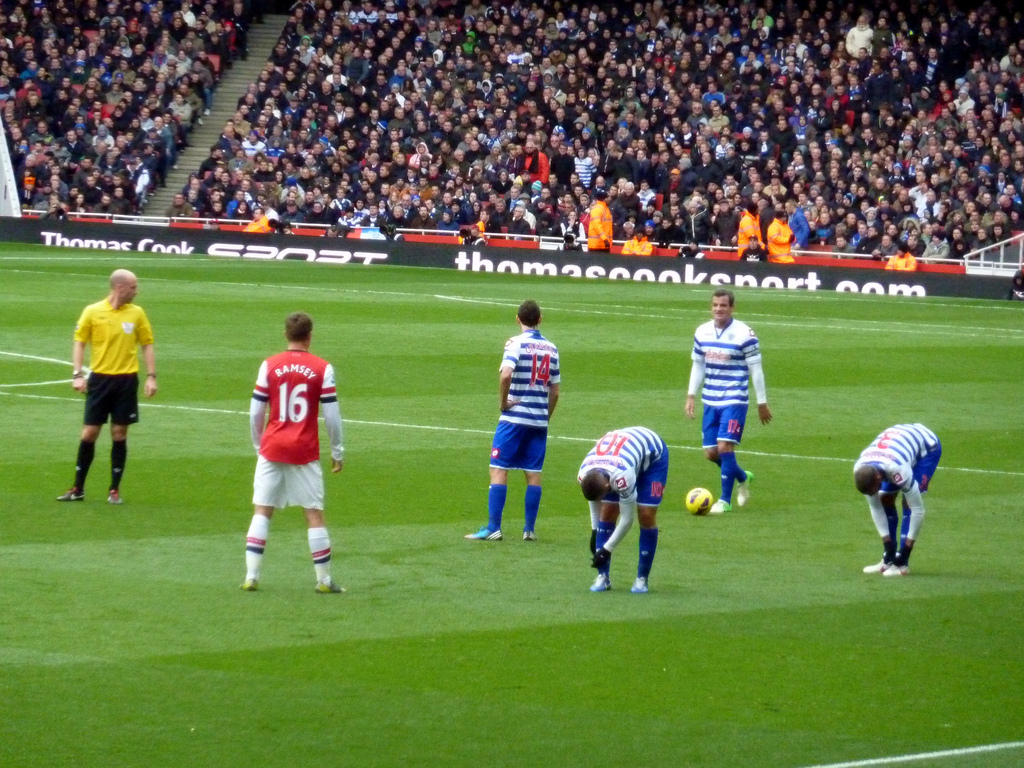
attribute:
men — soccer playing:
[226, 239, 964, 610]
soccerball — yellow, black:
[681, 485, 711, 520]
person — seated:
[649, 148, 673, 177]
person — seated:
[699, 103, 712, 143]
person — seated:
[650, 96, 664, 135]